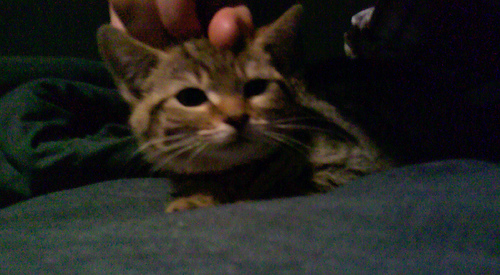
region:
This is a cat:
[83, 18, 391, 219]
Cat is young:
[72, 17, 407, 208]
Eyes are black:
[156, 63, 288, 117]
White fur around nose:
[191, 114, 286, 171]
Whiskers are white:
[129, 125, 341, 177]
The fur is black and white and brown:
[78, 15, 418, 214]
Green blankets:
[2, 32, 134, 184]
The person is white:
[101, 0, 286, 70]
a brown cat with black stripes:
[86, 3, 383, 225]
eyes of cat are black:
[166, 67, 275, 109]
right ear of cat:
[256, 4, 313, 64]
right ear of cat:
[86, 22, 172, 107]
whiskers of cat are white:
[117, 116, 329, 175]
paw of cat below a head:
[157, 178, 229, 220]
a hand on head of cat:
[89, 0, 356, 205]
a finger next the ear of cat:
[202, 2, 317, 77]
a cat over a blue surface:
[1, 9, 497, 267]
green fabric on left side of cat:
[3, 8, 392, 254]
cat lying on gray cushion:
[86, 5, 387, 267]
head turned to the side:
[101, 15, 381, 215]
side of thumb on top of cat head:
[205, 0, 255, 50]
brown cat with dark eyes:
[95, 0, 385, 212]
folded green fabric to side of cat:
[5, 46, 140, 196]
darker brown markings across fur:
[125, 36, 370, 197]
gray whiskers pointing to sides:
[120, 110, 315, 165]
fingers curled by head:
[110, 0, 196, 46]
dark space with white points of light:
[306, 2, 493, 159]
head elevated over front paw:
[128, 21, 296, 218]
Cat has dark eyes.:
[173, 70, 283, 87]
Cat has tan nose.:
[222, 106, 244, 131]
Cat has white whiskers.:
[143, 120, 203, 191]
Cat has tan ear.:
[93, 22, 164, 88]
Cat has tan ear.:
[261, 15, 320, 80]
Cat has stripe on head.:
[178, 43, 216, 88]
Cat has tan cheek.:
[139, 106, 184, 163]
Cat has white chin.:
[218, 128, 265, 160]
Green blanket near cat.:
[28, 73, 100, 145]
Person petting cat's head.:
[128, 8, 291, 38]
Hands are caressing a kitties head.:
[95, 3, 388, 218]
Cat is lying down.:
[87, 4, 396, 217]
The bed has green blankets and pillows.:
[2, 52, 495, 273]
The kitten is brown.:
[92, 8, 387, 216]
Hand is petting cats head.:
[94, 0, 304, 177]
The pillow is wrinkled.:
[2, 71, 149, 195]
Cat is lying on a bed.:
[1, 0, 497, 273]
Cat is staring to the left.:
[60, 0, 385, 212]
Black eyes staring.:
[157, 70, 288, 111]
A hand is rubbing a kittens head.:
[91, 4, 404, 216]